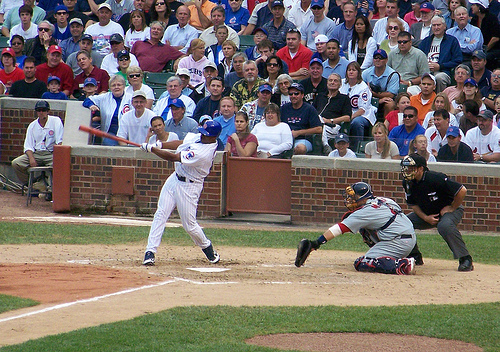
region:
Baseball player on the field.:
[48, 67, 253, 292]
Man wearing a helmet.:
[168, 92, 238, 214]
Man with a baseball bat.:
[71, 86, 265, 263]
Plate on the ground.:
[181, 244, 279, 305]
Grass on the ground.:
[190, 272, 390, 346]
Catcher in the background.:
[286, 137, 452, 290]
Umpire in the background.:
[388, 122, 473, 298]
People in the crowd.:
[127, 14, 312, 153]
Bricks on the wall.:
[59, 113, 196, 197]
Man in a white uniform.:
[50, 82, 351, 332]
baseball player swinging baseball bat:
[80, 119, 228, 266]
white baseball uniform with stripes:
[146, 131, 216, 248]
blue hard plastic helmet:
[197, 116, 221, 141]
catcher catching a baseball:
[294, 175, 414, 277]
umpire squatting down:
[396, 155, 474, 273]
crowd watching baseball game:
[2, 1, 499, 162]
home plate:
[189, 263, 231, 273]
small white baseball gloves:
[137, 138, 161, 155]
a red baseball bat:
[75, 125, 143, 149]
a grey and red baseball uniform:
[333, 185, 418, 267]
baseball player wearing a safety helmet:
[65, 95, 280, 275]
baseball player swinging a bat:
[67, 90, 259, 274]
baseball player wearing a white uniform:
[73, 110, 258, 281]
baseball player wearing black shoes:
[98, 73, 283, 273]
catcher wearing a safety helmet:
[279, 176, 425, 281]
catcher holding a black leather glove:
[274, 179, 421, 284]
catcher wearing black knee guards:
[286, 165, 416, 295]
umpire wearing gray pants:
[384, 140, 477, 280]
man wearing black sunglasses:
[367, 95, 439, 162]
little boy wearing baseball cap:
[306, 129, 369, 170]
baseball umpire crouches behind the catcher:
[398, 146, 478, 275]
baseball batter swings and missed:
[70, 111, 227, 270]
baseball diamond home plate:
[185, 261, 230, 276]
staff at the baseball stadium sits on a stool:
[10, 101, 62, 205]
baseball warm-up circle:
[242, 325, 490, 350]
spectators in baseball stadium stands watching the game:
[17, 0, 497, 157]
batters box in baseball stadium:
[152, 257, 384, 284]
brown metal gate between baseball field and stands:
[222, 153, 290, 215]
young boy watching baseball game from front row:
[326, 134, 355, 157]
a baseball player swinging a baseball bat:
[78, 120, 228, 265]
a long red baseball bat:
[77, 125, 147, 150]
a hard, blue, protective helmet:
[193, 119, 222, 138]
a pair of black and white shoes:
[139, 245, 219, 266]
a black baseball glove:
[292, 238, 314, 269]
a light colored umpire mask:
[399, 152, 421, 182]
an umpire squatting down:
[396, 155, 474, 272]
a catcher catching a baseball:
[294, 187, 415, 273]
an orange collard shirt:
[407, 92, 441, 126]